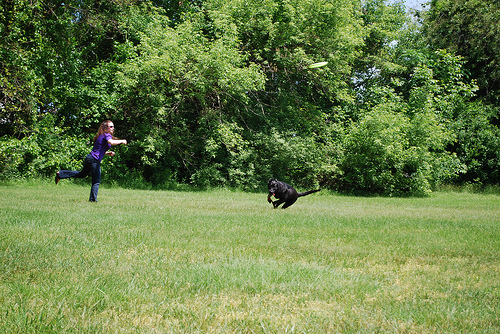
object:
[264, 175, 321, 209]
dog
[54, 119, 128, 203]
girl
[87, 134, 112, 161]
shirt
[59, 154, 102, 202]
jeans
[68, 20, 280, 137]
tree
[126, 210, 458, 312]
grass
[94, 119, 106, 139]
hair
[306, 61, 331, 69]
frisbee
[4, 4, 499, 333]
field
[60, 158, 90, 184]
leg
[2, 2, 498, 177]
forest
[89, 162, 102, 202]
leg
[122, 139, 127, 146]
hand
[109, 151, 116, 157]
hand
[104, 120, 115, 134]
head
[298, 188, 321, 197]
tail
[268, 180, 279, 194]
head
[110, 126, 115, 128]
sunglasses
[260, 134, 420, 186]
bush